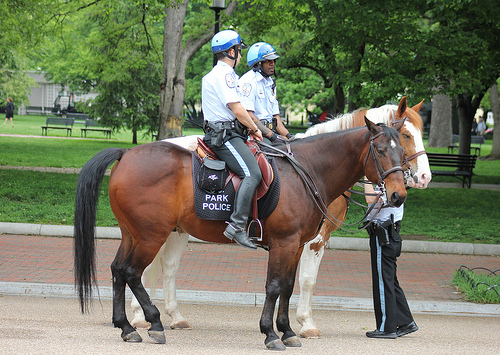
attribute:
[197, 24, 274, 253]
policeman — police, riding, sitting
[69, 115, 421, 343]
horse — brown, dark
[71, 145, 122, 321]
tail — black, long, brown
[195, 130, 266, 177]
pants — black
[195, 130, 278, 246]
saddle — brown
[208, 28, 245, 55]
helmet — police, blue, white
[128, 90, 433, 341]
horse — brown, white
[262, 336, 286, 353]
hoof — black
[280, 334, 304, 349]
hoof — black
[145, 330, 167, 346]
hoof — black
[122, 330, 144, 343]
hoof — black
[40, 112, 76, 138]
bench — black, green, sitting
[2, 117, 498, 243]
grass — green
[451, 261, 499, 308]
weeds — green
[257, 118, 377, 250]
reins — black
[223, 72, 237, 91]
insignia — police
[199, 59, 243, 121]
shirt — white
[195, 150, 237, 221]
bag — saddle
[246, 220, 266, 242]
stirrup — silver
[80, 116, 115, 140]
bench — black, green, sitting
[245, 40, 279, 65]
helmet — police, white, blue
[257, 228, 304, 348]
leg — black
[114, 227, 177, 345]
leg — black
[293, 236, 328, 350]
leg — white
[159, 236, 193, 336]
leg — white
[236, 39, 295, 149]
policeman — riding, sitting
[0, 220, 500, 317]
street — brick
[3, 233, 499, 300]
brick — red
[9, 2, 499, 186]
trees — full, green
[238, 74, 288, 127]
shirt — white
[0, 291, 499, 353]
sidewalk — grey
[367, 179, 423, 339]
officer — police, hidden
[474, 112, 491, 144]
person — walking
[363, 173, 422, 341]
policeman — standing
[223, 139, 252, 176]
stripe — blue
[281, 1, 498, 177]
tree — growing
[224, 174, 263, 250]
boots — knee